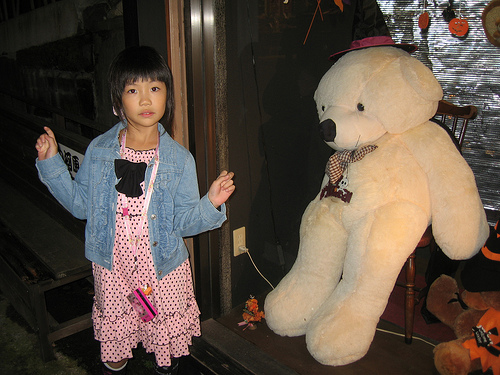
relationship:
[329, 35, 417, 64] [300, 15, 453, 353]
hat on bear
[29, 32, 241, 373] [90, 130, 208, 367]
girl wearing dress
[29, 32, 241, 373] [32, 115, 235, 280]
girl wearing denim jacket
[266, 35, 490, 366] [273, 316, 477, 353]
bear on floor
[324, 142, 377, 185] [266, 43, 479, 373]
bow on bear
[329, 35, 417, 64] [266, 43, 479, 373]
hat on bear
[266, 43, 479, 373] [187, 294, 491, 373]
bear on shelf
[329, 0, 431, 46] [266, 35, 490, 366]
hat on bear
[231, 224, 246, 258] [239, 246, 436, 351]
outlet with plugged in cord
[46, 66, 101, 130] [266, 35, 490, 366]
chair under bear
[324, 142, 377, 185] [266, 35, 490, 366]
bow on bear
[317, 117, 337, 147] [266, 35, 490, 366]
nose on bear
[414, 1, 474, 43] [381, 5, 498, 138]
pumpkin on window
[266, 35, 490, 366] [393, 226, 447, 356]
bear on chair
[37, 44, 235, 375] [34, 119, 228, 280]
girl in denim jacket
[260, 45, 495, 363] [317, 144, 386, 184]
ribbon on bear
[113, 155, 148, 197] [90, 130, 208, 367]
bow on dress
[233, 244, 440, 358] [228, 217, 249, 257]
cord plugged into outlet